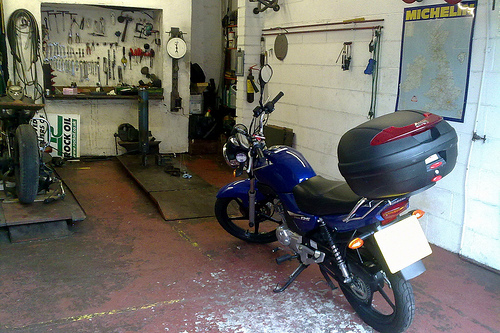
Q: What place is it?
A: It is a garage.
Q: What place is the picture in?
A: It is at the garage.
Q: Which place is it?
A: It is a garage.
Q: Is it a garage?
A: Yes, it is a garage.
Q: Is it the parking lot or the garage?
A: It is the garage.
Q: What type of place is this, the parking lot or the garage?
A: It is the garage.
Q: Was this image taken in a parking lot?
A: No, the picture was taken in a garage.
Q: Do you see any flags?
A: No, there are no flags.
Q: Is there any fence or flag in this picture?
A: No, there are no flags or fences.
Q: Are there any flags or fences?
A: No, there are no flags or fences.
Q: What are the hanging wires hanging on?
A: The wires are hanging on the wall.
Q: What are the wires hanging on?
A: The wires are hanging on the wall.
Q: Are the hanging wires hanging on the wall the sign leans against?
A: Yes, the wires are hanging on the wall.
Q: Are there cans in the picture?
A: No, there are no cans.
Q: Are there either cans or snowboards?
A: No, there are no cans or snowboards.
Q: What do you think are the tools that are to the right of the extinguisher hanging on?
A: The tools are hanging on the wall.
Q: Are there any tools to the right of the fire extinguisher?
A: Yes, there are tools to the right of the fire extinguisher.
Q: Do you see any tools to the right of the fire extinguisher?
A: Yes, there are tools to the right of the fire extinguisher.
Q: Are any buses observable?
A: No, there are no buses.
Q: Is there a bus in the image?
A: No, there are no buses.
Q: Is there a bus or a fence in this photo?
A: No, there are no buses or fences.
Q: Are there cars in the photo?
A: No, there are no cars.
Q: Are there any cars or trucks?
A: No, there are no cars or trucks.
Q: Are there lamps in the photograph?
A: No, there are no lamps.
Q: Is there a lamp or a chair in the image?
A: No, there are no lamps or chairs.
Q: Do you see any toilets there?
A: No, there are no toilets.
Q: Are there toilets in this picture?
A: No, there are no toilets.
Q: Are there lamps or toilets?
A: No, there are no toilets or lamps.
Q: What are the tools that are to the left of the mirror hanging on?
A: The tools are hanging on the wall.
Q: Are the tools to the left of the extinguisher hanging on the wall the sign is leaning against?
A: Yes, the tools are hanging on the wall.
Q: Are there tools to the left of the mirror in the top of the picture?
A: Yes, there are tools to the left of the mirror.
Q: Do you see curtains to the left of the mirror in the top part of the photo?
A: No, there are tools to the left of the mirror.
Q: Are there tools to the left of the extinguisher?
A: Yes, there are tools to the left of the extinguisher.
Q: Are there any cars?
A: No, there are no cars.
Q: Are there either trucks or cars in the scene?
A: No, there are no cars or trucks.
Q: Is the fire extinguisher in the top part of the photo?
A: Yes, the fire extinguisher is in the top of the image.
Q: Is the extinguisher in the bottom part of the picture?
A: No, the extinguisher is in the top of the image.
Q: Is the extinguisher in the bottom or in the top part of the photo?
A: The extinguisher is in the top of the image.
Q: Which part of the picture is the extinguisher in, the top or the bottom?
A: The extinguisher is in the top of the image.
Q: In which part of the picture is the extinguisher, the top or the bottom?
A: The extinguisher is in the top of the image.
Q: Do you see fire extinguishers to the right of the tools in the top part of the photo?
A: Yes, there is a fire extinguisher to the right of the tools.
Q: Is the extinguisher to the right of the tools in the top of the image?
A: Yes, the extinguisher is to the right of the tools.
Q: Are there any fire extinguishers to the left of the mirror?
A: Yes, there is a fire extinguisher to the left of the mirror.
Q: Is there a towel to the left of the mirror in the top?
A: No, there is a fire extinguisher to the left of the mirror.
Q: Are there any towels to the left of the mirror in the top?
A: No, there is a fire extinguisher to the left of the mirror.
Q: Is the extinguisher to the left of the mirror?
A: Yes, the extinguisher is to the left of the mirror.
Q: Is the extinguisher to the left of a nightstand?
A: No, the extinguisher is to the left of the mirror.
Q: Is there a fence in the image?
A: No, there are no fences.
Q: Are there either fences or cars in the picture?
A: No, there are no fences or cars.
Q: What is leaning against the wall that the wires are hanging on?
A: The sign is leaning against the wall.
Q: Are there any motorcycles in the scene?
A: Yes, there is a motorcycle.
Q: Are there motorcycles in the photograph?
A: Yes, there is a motorcycle.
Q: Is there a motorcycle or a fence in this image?
A: Yes, there is a motorcycle.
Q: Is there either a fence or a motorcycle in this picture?
A: Yes, there is a motorcycle.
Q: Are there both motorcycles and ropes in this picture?
A: No, there is a motorcycle but no ropes.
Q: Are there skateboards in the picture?
A: No, there are no skateboards.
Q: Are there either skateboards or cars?
A: No, there are no skateboards or cars.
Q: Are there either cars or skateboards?
A: No, there are no skateboards or cars.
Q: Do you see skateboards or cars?
A: No, there are no skateboards or cars.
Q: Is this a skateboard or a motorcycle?
A: This is a motorcycle.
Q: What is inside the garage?
A: The motorbike is inside the garage.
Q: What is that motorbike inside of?
A: The motorbike is inside the garage.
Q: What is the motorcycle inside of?
A: The motorbike is inside the garage.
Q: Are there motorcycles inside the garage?
A: Yes, there is a motorcycle inside the garage.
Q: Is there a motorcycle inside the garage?
A: Yes, there is a motorcycle inside the garage.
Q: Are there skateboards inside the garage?
A: No, there is a motorcycle inside the garage.